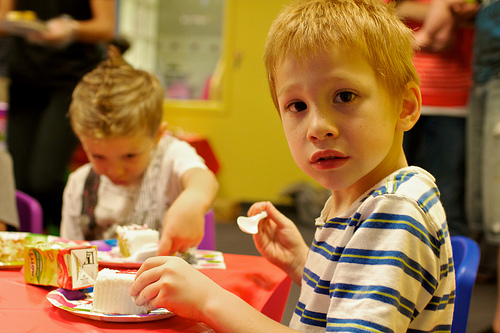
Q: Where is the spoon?
A: Boy's right hand.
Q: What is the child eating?
A: Cake.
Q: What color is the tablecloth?
A: Orange.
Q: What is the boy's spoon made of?
A: Plastic.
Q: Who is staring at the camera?
A: The boy.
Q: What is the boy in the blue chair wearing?
A: A striped shirt.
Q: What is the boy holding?
A: A spoon.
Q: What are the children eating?
A: Birthday cake.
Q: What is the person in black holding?
A: A plate.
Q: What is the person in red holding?
A: A baby.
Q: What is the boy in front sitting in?
A: A blue chair.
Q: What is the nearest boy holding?
A: A spoon.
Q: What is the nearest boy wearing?
A: A shirt.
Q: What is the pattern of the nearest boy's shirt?
A: Stripes.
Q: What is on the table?
A: Paper plates.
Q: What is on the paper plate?
A: Cake.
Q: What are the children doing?
A: Eating cake.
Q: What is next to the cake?
A: A juice box.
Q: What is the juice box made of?
A: Cardboard.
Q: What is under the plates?
A: A tablecloth.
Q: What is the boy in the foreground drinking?
A: Juicebox.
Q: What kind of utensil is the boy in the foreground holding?
A: Spoon.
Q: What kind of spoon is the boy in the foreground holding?
A: Plastic spoon.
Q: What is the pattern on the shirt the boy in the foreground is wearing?
A: Stripes.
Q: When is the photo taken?
A: Daytime.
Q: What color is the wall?
A: Yellow.